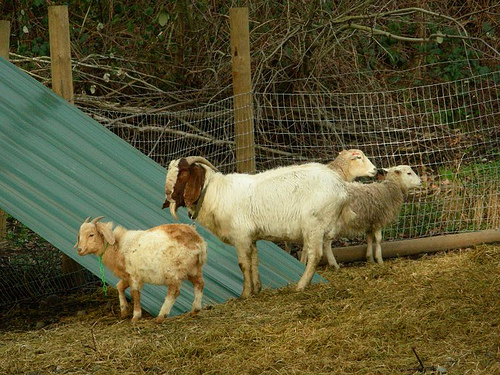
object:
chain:
[96, 254, 110, 296]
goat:
[161, 156, 357, 298]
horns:
[186, 155, 219, 172]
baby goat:
[73, 214, 209, 324]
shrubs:
[3, 1, 500, 89]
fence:
[6, 77, 499, 308]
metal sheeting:
[1, 61, 330, 316]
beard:
[168, 202, 180, 220]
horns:
[90, 215, 102, 224]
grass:
[3, 255, 498, 373]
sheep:
[299, 164, 422, 266]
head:
[163, 152, 220, 209]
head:
[74, 216, 117, 257]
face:
[164, 159, 189, 201]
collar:
[187, 183, 209, 220]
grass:
[372, 155, 497, 233]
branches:
[31, 50, 310, 144]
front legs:
[238, 242, 255, 294]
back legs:
[300, 233, 325, 280]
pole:
[230, 3, 257, 171]